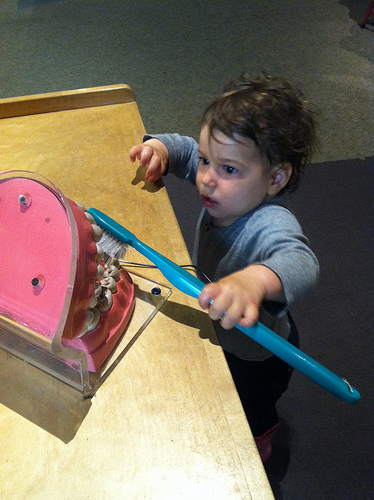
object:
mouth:
[199, 193, 220, 211]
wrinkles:
[255, 230, 315, 263]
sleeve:
[246, 205, 320, 312]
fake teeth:
[91, 287, 112, 310]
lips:
[201, 195, 219, 207]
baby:
[128, 74, 321, 479]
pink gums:
[0, 180, 138, 373]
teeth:
[87, 307, 100, 331]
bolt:
[30, 275, 40, 287]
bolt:
[17, 192, 29, 208]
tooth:
[94, 286, 102, 296]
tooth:
[84, 210, 96, 224]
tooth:
[75, 200, 87, 211]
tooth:
[96, 244, 104, 261]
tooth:
[89, 221, 102, 242]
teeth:
[95, 287, 112, 310]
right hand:
[129, 134, 168, 183]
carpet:
[270, 157, 373, 500]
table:
[1, 83, 275, 500]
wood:
[9, 119, 123, 165]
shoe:
[249, 406, 289, 479]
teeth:
[91, 223, 103, 242]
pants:
[224, 311, 299, 436]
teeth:
[211, 199, 214, 202]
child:
[119, 77, 322, 347]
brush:
[86, 199, 364, 407]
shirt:
[133, 126, 317, 316]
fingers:
[128, 145, 141, 163]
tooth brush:
[79, 199, 364, 402]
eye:
[222, 165, 239, 175]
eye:
[197, 153, 209, 166]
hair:
[206, 77, 320, 169]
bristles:
[97, 232, 126, 260]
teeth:
[102, 265, 120, 280]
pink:
[259, 437, 272, 456]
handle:
[150, 256, 361, 403]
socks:
[253, 425, 277, 458]